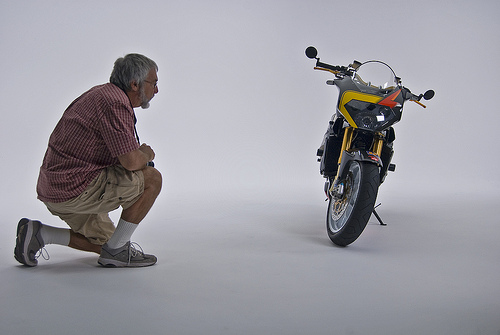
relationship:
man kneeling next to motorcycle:
[13, 50, 170, 270] [304, 40, 434, 244]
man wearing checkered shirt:
[13, 52, 163, 270] [34, 81, 140, 203]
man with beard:
[13, 50, 170, 270] [138, 79, 148, 107]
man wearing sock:
[13, 50, 170, 270] [105, 217, 138, 249]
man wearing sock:
[13, 50, 170, 270] [38, 219, 71, 246]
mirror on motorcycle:
[415, 88, 435, 102] [304, 40, 434, 244]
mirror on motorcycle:
[303, 46, 322, 63] [304, 40, 434, 244]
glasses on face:
[145, 77, 157, 88] [143, 72, 163, 105]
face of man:
[143, 72, 163, 105] [13, 50, 170, 270]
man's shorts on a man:
[40, 165, 145, 246] [13, 50, 170, 270]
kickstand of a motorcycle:
[372, 208, 389, 229] [304, 40, 434, 244]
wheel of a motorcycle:
[321, 149, 383, 250] [304, 40, 434, 244]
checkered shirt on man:
[33, 77, 139, 201] [13, 50, 170, 270]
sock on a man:
[95, 221, 134, 253] [13, 50, 170, 270]